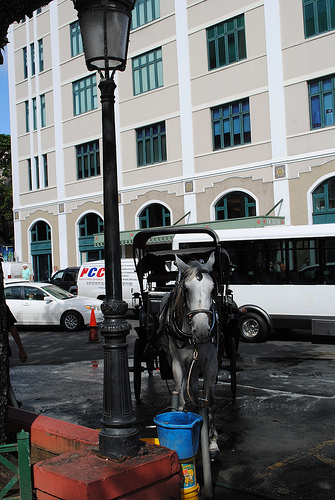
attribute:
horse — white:
[157, 248, 231, 452]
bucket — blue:
[153, 405, 203, 463]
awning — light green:
[89, 208, 285, 248]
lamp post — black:
[68, 2, 145, 461]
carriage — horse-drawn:
[127, 218, 247, 418]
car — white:
[0, 252, 101, 330]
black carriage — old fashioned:
[128, 223, 244, 408]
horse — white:
[148, 250, 232, 454]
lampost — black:
[87, 77, 134, 467]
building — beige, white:
[4, 0, 334, 290]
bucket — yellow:
[180, 461, 204, 498]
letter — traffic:
[87, 308, 98, 344]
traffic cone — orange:
[86, 307, 98, 326]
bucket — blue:
[147, 412, 228, 469]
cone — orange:
[84, 307, 101, 328]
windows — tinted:
[179, 236, 331, 287]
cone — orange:
[79, 295, 117, 345]